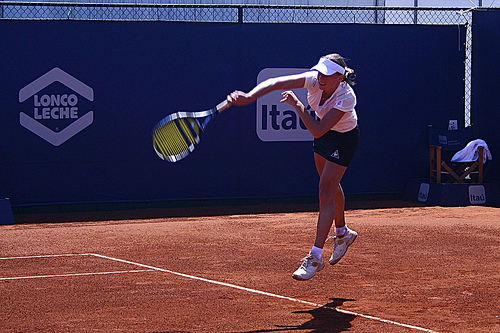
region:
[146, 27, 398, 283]
woman playing tennis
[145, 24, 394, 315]
lady is leaping in air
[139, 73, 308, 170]
backhand swing with right arm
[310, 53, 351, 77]
white visor on head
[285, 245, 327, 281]
dirty white tennis shoes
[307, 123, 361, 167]
pair of black shorts with white logo on left leg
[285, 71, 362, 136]
white tee with white logo patch on left sleeve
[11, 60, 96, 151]
white logo printed on blue barrier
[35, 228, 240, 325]
tennis court is dirt with white lines painted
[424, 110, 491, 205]
blue canvas chair with a white towel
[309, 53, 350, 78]
White visor of person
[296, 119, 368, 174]
Black shorts on person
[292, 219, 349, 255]
White socks on person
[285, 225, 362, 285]
White shoes on person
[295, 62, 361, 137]
White shirt on person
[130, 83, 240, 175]
Tennis racket in player's hand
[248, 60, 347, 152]
White logo on blue wall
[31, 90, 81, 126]
Words "Loncho Leche" on blue wall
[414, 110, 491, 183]
Chair against blue wall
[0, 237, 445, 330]
White lines on ground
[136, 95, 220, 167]
Yellow and blue tennis racket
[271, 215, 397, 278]
White tennis shoes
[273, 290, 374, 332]
Shadow cast by a female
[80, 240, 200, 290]
White lines on the pavement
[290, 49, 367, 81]
Small white sun visor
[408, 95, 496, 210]
Blue and white chair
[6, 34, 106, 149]
White lettering on blue background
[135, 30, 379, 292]
Woman jumping in the air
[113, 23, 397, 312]
Woman holding a tennis racket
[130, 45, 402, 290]
Woman wearing a black skirt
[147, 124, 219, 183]
yellow part of racquet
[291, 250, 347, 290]
left shoe of tennis player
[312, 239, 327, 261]
white sock of player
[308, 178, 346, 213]
left knee of woman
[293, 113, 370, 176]
navy blue shorts of woman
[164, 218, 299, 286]
clay surface of court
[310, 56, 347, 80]
white visor of tennis player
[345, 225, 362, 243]
back of right shoe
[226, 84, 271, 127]
right hand of player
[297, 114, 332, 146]
left elbow of player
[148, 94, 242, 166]
blue and yellow tennis racket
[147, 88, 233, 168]
tennis racket with yellow net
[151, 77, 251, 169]
hand holding tennis racket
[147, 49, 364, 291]
woman hitting tennis ball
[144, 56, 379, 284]
woman swinging tennis racket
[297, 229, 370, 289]
white tennis shoes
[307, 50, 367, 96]
white tennis visor on head of woman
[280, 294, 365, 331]
black shadow n the ground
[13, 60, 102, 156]
sponsor logo on side of wall